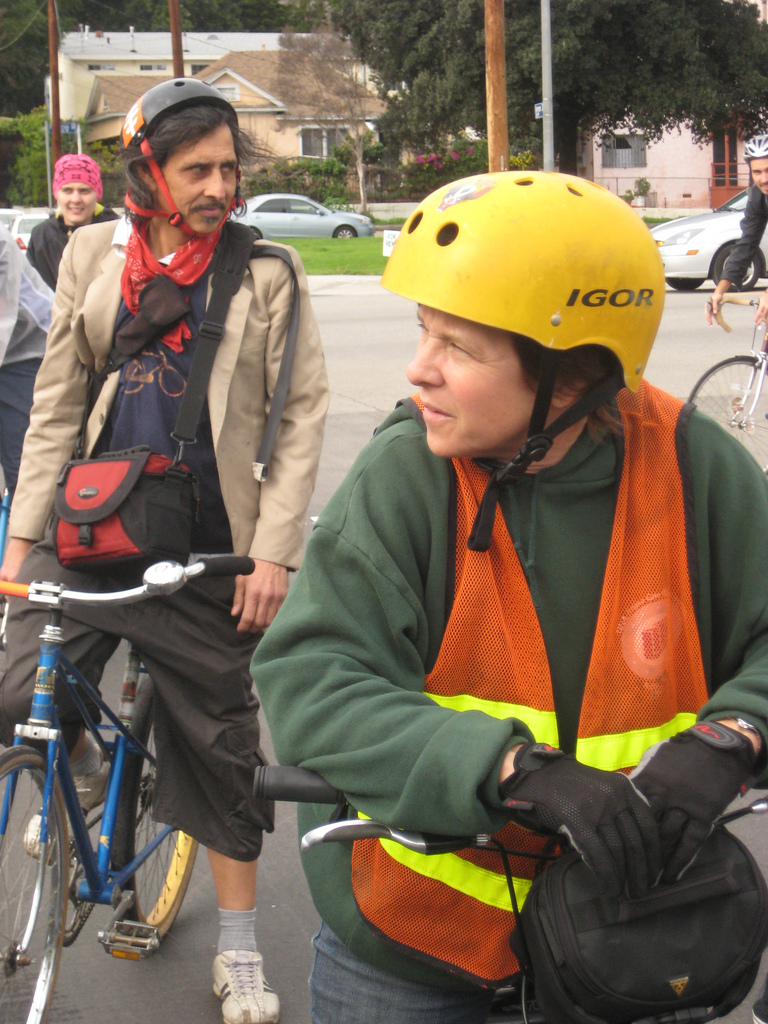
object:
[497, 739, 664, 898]
glove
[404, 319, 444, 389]
nose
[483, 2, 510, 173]
pole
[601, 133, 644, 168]
window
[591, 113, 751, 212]
house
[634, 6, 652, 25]
leaves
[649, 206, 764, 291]
front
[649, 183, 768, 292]
car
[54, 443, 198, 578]
bag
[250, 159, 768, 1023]
man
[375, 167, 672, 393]
helmet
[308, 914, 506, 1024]
jeans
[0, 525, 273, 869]
shorts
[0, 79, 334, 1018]
man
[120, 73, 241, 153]
helmet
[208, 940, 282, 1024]
shoe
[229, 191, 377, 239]
vehicle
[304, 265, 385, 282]
curbside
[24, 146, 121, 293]
woman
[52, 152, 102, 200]
hat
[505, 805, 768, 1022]
bag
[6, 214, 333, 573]
suit jacket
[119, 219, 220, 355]
scarf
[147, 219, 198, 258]
neck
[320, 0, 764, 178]
tree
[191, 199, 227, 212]
mustache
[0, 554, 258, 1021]
bicycle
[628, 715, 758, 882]
gloves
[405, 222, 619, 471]
head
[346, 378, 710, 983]
safety vest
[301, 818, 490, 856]
handlebars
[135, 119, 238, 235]
face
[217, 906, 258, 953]
socks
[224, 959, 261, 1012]
lace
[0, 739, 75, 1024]
tire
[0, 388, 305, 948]
road